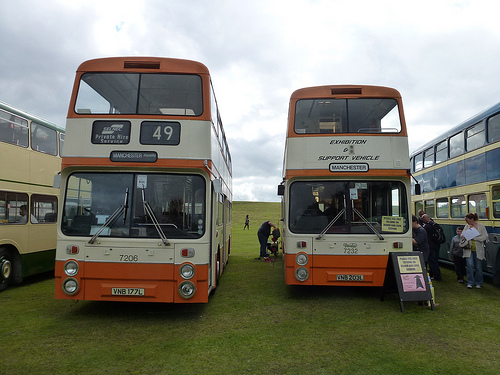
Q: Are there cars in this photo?
A: No, there are no cars.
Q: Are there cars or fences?
A: No, there are no cars or fences.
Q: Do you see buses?
A: Yes, there is a bus.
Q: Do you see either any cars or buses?
A: Yes, there is a bus.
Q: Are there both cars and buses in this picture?
A: No, there is a bus but no cars.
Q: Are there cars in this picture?
A: No, there are no cars.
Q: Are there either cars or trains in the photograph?
A: No, there are no cars or trains.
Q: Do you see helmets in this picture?
A: No, there are no helmets.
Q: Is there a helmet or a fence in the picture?
A: No, there are no helmets or fences.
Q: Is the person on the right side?
A: Yes, the person is on the right of the image.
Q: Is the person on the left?
A: No, the person is on the right of the image.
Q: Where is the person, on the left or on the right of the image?
A: The person is on the right of the image.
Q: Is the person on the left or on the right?
A: The person is on the right of the image.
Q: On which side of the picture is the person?
A: The person is on the right of the image.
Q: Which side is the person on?
A: The person is on the right of the image.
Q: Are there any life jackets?
A: No, there are no life jackets.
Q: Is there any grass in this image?
A: Yes, there is grass.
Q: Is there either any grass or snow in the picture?
A: Yes, there is grass.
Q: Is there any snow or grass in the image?
A: Yes, there is grass.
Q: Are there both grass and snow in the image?
A: No, there is grass but no snow.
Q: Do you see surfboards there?
A: No, there are no surfboards.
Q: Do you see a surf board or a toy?
A: No, there are no surfboards or toys.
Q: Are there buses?
A: Yes, there is a bus.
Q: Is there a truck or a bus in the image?
A: Yes, there is a bus.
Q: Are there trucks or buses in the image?
A: Yes, there is a bus.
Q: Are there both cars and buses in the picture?
A: No, there is a bus but no cars.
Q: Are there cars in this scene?
A: No, there are no cars.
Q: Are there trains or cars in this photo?
A: No, there are no cars or trains.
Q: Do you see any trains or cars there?
A: No, there are no cars or trains.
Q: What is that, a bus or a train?
A: That is a bus.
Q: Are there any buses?
A: Yes, there is a bus.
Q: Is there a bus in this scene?
A: Yes, there is a bus.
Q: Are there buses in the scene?
A: Yes, there is a bus.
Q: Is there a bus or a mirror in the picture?
A: Yes, there is a bus.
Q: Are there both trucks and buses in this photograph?
A: No, there is a bus but no trucks.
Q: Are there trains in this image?
A: No, there are no trains.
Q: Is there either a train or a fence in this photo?
A: No, there are no trains or fences.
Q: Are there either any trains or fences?
A: No, there are no trains or fences.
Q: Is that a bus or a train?
A: That is a bus.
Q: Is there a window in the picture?
A: Yes, there is a window.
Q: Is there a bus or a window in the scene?
A: Yes, there is a window.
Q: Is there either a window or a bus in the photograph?
A: Yes, there is a window.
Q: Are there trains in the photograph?
A: No, there are no trains.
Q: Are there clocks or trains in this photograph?
A: No, there are no trains or clocks.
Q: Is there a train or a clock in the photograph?
A: No, there are no trains or clocks.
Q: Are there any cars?
A: No, there are no cars.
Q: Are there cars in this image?
A: No, there are no cars.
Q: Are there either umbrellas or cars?
A: No, there are no cars or umbrellas.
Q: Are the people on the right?
A: Yes, the people are on the right of the image.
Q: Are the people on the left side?
A: No, the people are on the right of the image.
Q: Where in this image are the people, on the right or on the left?
A: The people are on the right of the image.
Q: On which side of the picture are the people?
A: The people are on the right of the image.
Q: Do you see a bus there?
A: Yes, there is a bus.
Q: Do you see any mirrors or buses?
A: Yes, there is a bus.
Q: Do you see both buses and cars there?
A: No, there is a bus but no cars.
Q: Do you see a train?
A: No, there are no trains.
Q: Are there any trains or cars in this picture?
A: No, there are no trains or cars.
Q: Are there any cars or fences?
A: No, there are no cars or fences.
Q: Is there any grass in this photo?
A: Yes, there is grass.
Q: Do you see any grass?
A: Yes, there is grass.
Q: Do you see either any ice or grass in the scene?
A: Yes, there is grass.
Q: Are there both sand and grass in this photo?
A: No, there is grass but no sand.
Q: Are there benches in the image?
A: No, there are no benches.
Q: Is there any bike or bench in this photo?
A: No, there are no benches or bikes.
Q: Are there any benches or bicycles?
A: No, there are no benches or bicycles.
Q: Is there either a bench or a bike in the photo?
A: No, there are no benches or bikes.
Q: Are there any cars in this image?
A: No, there are no cars.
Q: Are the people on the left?
A: No, the people are on the right of the image.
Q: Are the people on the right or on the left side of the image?
A: The people are on the right of the image.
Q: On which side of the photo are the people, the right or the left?
A: The people are on the right of the image.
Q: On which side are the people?
A: The people are on the right of the image.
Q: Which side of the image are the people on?
A: The people are on the right of the image.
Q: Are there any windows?
A: Yes, there are windows.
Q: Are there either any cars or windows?
A: Yes, there are windows.